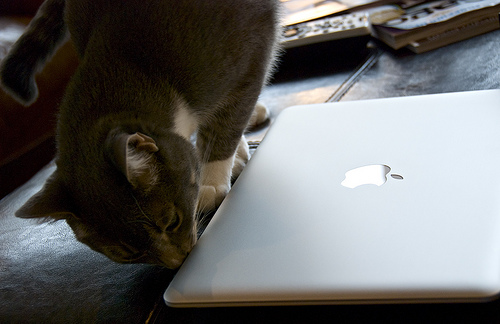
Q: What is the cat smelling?
A: Laptop.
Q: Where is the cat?
A: Next to the computer.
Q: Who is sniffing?
A: The cat.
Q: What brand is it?
A: Apple.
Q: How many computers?
A: One.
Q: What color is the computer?
A: Gray.